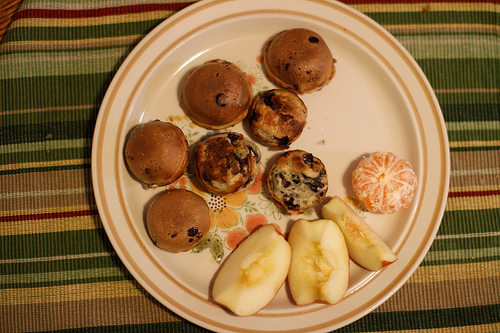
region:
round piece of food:
[259, 18, 343, 92]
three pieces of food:
[175, 33, 333, 143]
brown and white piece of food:
[271, 142, 338, 214]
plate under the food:
[326, 95, 388, 153]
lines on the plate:
[400, 70, 442, 134]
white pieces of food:
[201, 196, 386, 315]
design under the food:
[212, 190, 274, 233]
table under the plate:
[0, 197, 85, 284]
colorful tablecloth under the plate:
[13, 169, 81, 295]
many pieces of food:
[126, 37, 446, 321]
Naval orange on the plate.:
[341, 149, 425, 215]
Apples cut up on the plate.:
[204, 190, 393, 321]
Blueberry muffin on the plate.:
[252, 125, 343, 226]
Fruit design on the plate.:
[152, 145, 270, 251]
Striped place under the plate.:
[4, 21, 99, 153]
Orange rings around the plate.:
[375, 25, 448, 111]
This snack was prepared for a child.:
[198, 129, 422, 316]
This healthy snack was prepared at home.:
[193, 145, 416, 308]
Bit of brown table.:
[0, 6, 40, 32]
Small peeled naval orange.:
[345, 140, 422, 211]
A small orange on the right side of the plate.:
[351, 151, 418, 215]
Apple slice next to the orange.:
[323, 195, 399, 269]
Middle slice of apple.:
[284, 213, 349, 306]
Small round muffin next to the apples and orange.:
[266, 148, 328, 213]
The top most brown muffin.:
[263, 26, 337, 91]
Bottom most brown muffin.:
[144, 190, 211, 252]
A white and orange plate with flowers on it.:
[90, 0, 450, 332]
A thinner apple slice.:
[321, 195, 398, 270]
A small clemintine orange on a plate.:
[349, 152, 416, 214]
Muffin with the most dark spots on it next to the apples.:
[266, 150, 330, 212]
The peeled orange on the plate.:
[365, 150, 412, 211]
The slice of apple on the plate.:
[325, 195, 397, 270]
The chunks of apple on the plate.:
[220, 215, 340, 300]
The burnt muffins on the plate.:
[200, 93, 330, 203]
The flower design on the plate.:
[172, 110, 274, 255]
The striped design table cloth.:
[10, 7, 495, 331]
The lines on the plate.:
[116, 14, 435, 291]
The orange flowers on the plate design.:
[223, 170, 283, 240]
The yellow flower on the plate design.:
[185, 175, 250, 227]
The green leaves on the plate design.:
[190, 195, 273, 262]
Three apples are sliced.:
[198, 215, 390, 290]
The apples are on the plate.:
[204, 206, 391, 292]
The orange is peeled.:
[345, 153, 417, 213]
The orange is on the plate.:
[343, 153, 418, 208]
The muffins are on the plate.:
[105, 16, 335, 213]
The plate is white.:
[87, 3, 469, 331]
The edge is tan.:
[81, 0, 456, 330]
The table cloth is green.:
[6, 1, 113, 331]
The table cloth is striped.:
[0, 6, 117, 328]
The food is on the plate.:
[95, 25, 449, 332]